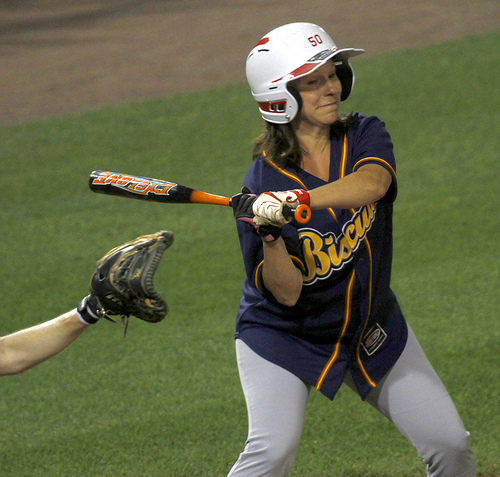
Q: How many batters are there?
A: One.